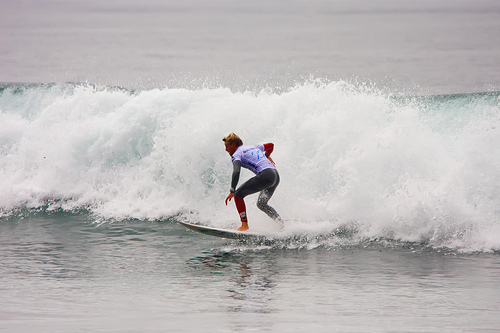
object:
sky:
[1, 0, 500, 27]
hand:
[224, 192, 234, 206]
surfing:
[176, 133, 281, 243]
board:
[176, 219, 287, 239]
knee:
[234, 193, 239, 197]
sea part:
[142, 53, 162, 62]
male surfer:
[178, 131, 286, 239]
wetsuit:
[226, 143, 287, 231]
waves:
[3, 82, 500, 254]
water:
[0, 10, 500, 333]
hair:
[221, 132, 243, 147]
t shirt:
[231, 144, 277, 175]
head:
[222, 132, 244, 155]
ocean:
[0, 0, 497, 333]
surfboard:
[177, 220, 281, 240]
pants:
[234, 168, 284, 223]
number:
[251, 149, 264, 158]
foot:
[235, 221, 250, 231]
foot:
[271, 219, 288, 232]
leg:
[234, 170, 277, 224]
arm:
[229, 157, 242, 193]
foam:
[0, 83, 495, 244]